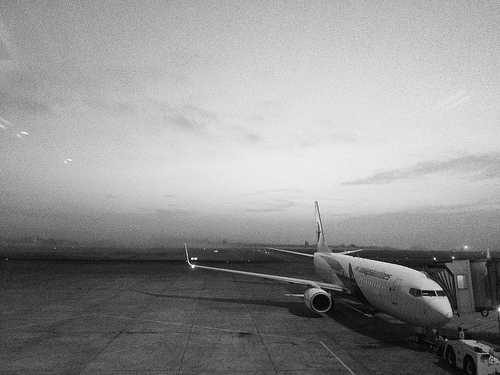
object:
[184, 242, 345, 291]
wing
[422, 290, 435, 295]
windshield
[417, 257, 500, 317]
exit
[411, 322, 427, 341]
people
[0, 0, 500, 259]
sky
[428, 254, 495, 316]
ramp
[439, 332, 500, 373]
vehicle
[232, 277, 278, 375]
crack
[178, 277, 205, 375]
crack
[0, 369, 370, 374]
crack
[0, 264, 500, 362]
road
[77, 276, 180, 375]
crack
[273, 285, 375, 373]
crack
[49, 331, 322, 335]
crack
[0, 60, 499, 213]
cloud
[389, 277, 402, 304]
door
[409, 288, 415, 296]
window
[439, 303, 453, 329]
nose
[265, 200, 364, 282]
tail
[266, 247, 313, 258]
tail wing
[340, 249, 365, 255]
tail wing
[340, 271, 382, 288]
passenger windows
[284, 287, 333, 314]
engine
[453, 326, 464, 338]
person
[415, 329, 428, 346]
people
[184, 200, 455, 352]
airplane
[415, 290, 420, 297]
windows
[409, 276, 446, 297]
cockpit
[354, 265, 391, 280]
lettering